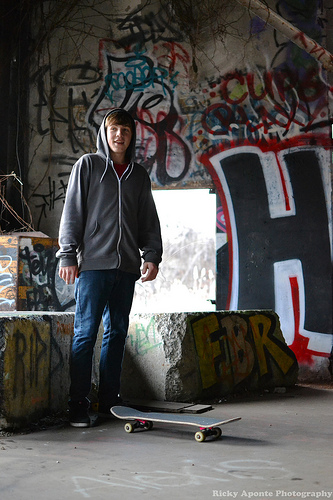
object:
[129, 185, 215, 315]
open doorway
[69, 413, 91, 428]
shoe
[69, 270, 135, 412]
jeans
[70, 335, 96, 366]
knee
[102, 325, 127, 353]
knee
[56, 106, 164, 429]
boy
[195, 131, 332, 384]
letter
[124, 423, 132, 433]
wheel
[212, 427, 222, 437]
wheels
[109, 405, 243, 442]
board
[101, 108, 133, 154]
hood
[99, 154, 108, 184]
string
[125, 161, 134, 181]
string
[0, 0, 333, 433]
graffiti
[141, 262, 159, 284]
hand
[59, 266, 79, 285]
hand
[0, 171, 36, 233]
tangle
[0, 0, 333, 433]
walls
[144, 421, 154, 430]
wheels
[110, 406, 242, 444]
skateboard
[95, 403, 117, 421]
sneaker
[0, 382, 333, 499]
alexis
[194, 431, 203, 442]
wheel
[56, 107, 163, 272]
hoodie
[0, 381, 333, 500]
ground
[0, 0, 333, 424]
concrete